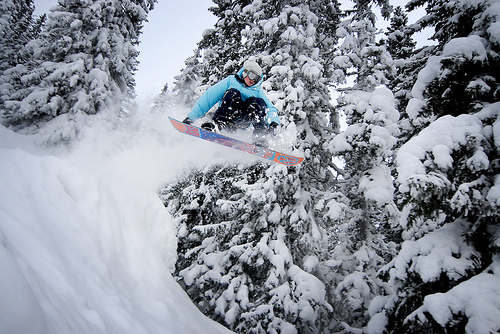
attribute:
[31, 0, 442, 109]
sky — light blue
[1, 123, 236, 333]
hill — steep, covered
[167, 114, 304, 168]
snowboard — colorful, orange, blue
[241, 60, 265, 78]
hat — white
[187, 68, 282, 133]
jacket — light blue, blue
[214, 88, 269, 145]
pants — black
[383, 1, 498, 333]
tree — evergreen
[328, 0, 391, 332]
tree — evergreen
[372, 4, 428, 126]
tree — evergreen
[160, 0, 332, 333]
tree — evergreen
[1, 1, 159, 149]
tree — evergreen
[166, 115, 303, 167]
designs — colorful